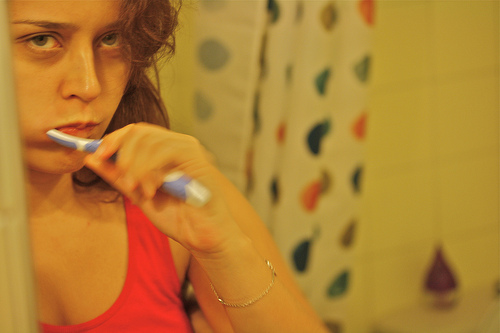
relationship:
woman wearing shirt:
[0, 0, 332, 333] [36, 193, 192, 331]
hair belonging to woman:
[70, 0, 185, 203] [0, 0, 332, 333]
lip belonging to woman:
[54, 121, 99, 134] [0, 0, 332, 333]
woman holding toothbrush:
[0, 0, 332, 333] [45, 127, 211, 207]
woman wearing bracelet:
[0, 0, 332, 333] [207, 257, 278, 308]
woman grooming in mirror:
[0, 0, 332, 333] [2, 0, 484, 330]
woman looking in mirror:
[0, 0, 332, 333] [2, 0, 484, 330]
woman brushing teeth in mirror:
[0, 0, 332, 333] [2, 0, 484, 330]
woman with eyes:
[6, 6, 287, 328] [13, 20, 121, 55]